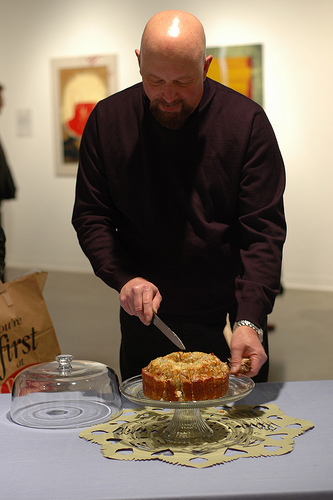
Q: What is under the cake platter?
A: A placemat.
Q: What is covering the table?
A: A white cloth.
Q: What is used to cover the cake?
A: A glass dome.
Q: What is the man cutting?
A: A cake.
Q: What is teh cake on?
A: A platter.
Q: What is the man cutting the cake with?
A: A knife.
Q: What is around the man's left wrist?
A: A watch.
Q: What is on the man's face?
A: A goatee.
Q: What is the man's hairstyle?
A: Bald.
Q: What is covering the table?
A: A white tablecloth.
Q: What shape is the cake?
A: Round.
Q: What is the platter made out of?
A: Glass.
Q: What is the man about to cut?
A: A cake.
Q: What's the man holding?
A: A knife.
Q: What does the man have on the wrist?
A: A watch,.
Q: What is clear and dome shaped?
A: The lid.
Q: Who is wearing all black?
A: The man.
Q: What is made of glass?
A: The cake cover.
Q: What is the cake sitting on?
A: A glass plate.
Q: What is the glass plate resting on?
A: A decorative place mat.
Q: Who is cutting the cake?
A: A man.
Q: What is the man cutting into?
A: Cake.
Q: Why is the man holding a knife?
A: To cut the cake.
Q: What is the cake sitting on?
A: Cake plate.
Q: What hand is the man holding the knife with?
A: Right hand.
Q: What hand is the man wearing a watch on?
A: Left hand.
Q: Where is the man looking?
A: At the cake.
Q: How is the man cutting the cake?
A: With a knife.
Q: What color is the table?
A: Purple.